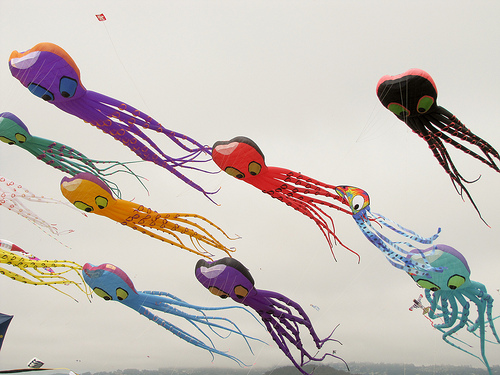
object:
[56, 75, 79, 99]
eyes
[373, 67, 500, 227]
kite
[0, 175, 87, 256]
kite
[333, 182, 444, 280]
tie-dye kite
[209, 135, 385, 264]
squid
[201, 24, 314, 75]
air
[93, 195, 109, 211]
eyes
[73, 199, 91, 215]
eyes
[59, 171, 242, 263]
kite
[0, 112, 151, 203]
kite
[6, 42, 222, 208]
kite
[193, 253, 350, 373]
kite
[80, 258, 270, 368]
kite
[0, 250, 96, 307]
kite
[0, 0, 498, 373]
sky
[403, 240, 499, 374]
kite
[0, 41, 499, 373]
several kites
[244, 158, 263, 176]
eyes